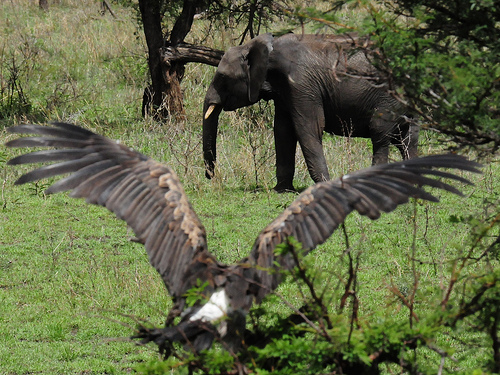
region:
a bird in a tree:
[8, 108, 478, 365]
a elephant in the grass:
[198, 24, 425, 188]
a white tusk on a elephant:
[199, 104, 222, 124]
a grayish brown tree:
[133, 1, 192, 124]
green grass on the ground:
[15, 214, 107, 352]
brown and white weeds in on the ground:
[23, 11, 121, 75]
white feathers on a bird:
[196, 289, 233, 331]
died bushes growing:
[160, 113, 200, 169]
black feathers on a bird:
[10, 125, 126, 197]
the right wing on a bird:
[251, 143, 483, 298]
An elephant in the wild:
[200, 35, 435, 185]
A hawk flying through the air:
[6, 110, 483, 357]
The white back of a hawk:
[199, 282, 234, 335]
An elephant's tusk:
[201, 102, 216, 118]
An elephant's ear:
[242, 39, 272, 103]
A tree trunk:
[135, 0, 231, 126]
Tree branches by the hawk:
[148, 221, 498, 373]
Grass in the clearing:
[0, 2, 482, 371]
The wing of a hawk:
[250, 150, 483, 290]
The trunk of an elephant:
[200, 107, 223, 179]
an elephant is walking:
[149, 14, 481, 226]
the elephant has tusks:
[182, 92, 234, 129]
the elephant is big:
[148, 25, 420, 173]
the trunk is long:
[182, 80, 235, 197]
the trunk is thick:
[176, 80, 247, 177]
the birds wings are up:
[10, 92, 460, 352]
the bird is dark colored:
[0, 91, 455, 316]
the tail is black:
[130, 315, 195, 355]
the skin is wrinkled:
[288, 47, 343, 95]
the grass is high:
[31, 25, 149, 139]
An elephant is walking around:
[35, 15, 497, 345]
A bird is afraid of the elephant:
[1, 32, 489, 372]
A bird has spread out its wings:
[7, 48, 488, 365]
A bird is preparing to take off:
[7, 92, 497, 357]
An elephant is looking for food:
[25, 17, 490, 367]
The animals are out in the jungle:
[25, 13, 498, 354]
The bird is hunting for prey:
[3, 16, 498, 356]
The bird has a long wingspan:
[0, 8, 498, 359]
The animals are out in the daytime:
[20, 12, 493, 367]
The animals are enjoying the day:
[10, 7, 497, 354]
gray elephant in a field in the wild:
[197, 26, 429, 206]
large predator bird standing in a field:
[2, 116, 481, 341]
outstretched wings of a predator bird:
[3, 117, 482, 306]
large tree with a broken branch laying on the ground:
[131, 0, 495, 160]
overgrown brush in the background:
[2, 0, 137, 123]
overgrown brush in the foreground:
[157, 171, 494, 371]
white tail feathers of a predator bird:
[190, 287, 230, 343]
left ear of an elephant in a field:
[249, 26, 306, 96]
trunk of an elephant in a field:
[193, 85, 220, 179]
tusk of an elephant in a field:
[200, 103, 217, 123]